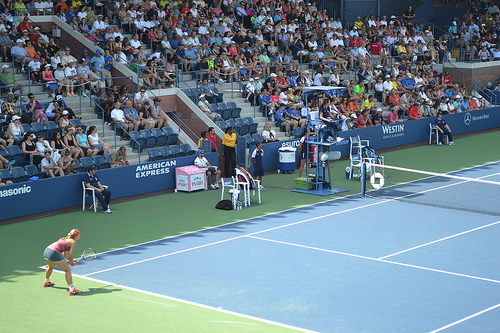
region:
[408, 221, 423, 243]
p-art of a court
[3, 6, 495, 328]
tthe game is tennis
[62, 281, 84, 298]
the shoes are pinnk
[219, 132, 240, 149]
the shirt is yellow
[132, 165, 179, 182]
the sponsor is american express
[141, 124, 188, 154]
the chairs are empty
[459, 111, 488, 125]
mercedes logo is on the wall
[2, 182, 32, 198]
panasonic iis advertised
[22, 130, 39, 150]
the woman has glasses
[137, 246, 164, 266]
the lines are white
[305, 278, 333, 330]
part of a court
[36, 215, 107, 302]
a girl bending over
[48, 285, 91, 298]
a right foot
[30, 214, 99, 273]
a girl holding a racket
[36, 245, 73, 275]
a short blue skirt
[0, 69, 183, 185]
people sitting in the stands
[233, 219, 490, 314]
this is the tennis court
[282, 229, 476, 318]
the tennis court is blue with strips of white in colour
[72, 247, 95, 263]
this is a tennis racket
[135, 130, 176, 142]
these are the chairs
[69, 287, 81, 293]
these are her shoes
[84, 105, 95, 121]
these are the stairs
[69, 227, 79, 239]
this is her head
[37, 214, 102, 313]
a woman playing tennis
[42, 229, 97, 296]
woman standing with tennis racket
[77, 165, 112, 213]
score keep watching tennis court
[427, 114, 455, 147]
score keep watching tennis court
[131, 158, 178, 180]
American Express business logo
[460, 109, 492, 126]
Mercedes Benz business logo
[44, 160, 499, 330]
large green tennis court with stripes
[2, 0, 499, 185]
audience watching a tennis match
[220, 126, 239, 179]
person wearing yellow shirt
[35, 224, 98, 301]
tennis player waiting for the serve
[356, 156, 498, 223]
net on a tennis court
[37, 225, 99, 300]
Tennis player in pink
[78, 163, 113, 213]
man in blue sitting in chair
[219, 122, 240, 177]
person in yellow shirt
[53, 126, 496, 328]
blue part of court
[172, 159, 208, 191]
evian water container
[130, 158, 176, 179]
wall text that read american express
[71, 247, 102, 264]
racket the woman is holding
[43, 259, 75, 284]
legs of the player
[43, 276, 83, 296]
shoes of the player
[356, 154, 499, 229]
the tennis court net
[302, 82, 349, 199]
the tennis ref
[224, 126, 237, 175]
a woman in yellow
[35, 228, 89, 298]
Tennis player wearing pink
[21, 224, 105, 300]
Tennis player holding a raquet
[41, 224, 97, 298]
Tennis player with a headband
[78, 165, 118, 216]
Man sitting in a chair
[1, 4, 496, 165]
People sitting in the stands.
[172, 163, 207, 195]
Pink and white box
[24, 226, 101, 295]
Tennis player wearing a skirt.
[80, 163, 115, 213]
Man wearing a blue hat.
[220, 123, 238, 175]
Woman standing up wearing yellow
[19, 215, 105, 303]
this is a tennis player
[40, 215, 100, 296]
player is bent down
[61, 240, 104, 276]
player holding a racket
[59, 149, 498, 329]
a blue and white tennis court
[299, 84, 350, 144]
linesman next to court